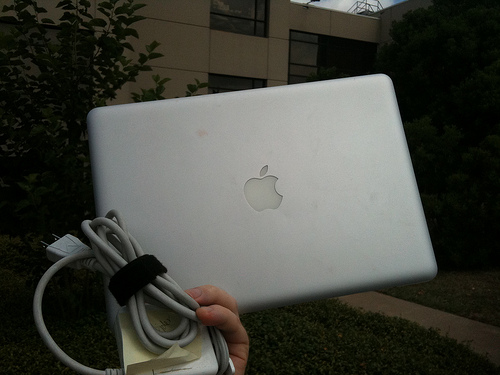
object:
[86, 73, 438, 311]
laptop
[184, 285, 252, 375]
hand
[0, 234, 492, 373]
grass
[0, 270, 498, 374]
ground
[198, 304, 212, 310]
fingernail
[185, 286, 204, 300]
fingernail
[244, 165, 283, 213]
logo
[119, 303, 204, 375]
post it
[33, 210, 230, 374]
cord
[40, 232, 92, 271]
plug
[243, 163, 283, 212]
apple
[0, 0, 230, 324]
bush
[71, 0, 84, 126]
branches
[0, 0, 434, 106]
building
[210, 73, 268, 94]
windows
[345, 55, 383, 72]
structure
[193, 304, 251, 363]
fingers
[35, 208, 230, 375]
wires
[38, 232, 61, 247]
prong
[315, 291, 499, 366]
ledge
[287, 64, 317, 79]
panes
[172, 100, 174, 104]
columns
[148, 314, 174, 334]
note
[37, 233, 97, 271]
charger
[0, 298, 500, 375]
bush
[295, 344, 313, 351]
leaf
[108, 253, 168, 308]
strap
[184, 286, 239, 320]
fingers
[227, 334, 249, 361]
wrinkles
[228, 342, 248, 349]
skin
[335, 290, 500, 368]
sidewalk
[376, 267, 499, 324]
grass patch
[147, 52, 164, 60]
leaf